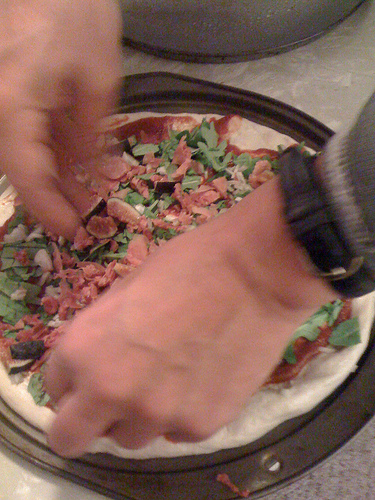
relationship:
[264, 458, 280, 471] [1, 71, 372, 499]
hole in pan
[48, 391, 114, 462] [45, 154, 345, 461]
finger on hand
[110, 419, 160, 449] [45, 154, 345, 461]
finger on hand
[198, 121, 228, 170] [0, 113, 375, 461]
leaf on pizza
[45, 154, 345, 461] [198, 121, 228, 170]
hand near leaf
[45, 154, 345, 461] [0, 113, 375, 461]
hand making pizza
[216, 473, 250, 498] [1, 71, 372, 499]
topping on pan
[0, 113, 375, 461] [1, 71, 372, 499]
pizza on pan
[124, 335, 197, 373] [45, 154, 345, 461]
vein on hand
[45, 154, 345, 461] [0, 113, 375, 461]
hand touching pizza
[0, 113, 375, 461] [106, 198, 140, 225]
pizza has topping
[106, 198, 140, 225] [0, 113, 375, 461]
topping on pizza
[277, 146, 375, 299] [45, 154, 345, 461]
watch on hand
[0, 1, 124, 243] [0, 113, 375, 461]
hand touching pizza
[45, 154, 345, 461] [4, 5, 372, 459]
hand on person